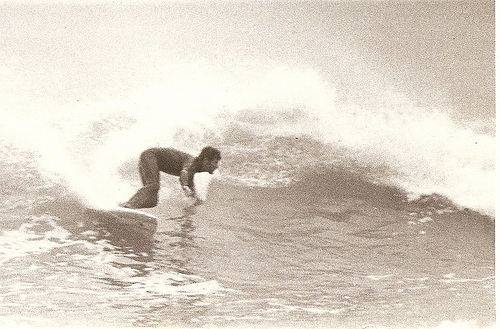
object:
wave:
[393, 73, 495, 219]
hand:
[181, 185, 192, 198]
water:
[247, 248, 492, 281]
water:
[1, 49, 412, 147]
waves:
[147, 41, 174, 137]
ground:
[441, 130, 458, 170]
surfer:
[118, 145, 221, 208]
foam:
[0, 213, 222, 325]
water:
[1, 301, 496, 326]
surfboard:
[87, 205, 157, 219]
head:
[198, 145, 220, 175]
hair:
[198, 146, 222, 160]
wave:
[2, 249, 143, 324]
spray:
[385, 2, 498, 175]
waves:
[2, 0, 39, 26]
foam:
[0, 70, 155, 160]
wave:
[8, 88, 140, 194]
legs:
[127, 149, 159, 209]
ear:
[200, 156, 208, 166]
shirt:
[159, 147, 199, 189]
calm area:
[202, 181, 474, 311]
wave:
[242, 60, 286, 139]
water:
[483, 2, 499, 216]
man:
[127, 146, 222, 209]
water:
[35, 129, 123, 204]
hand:
[192, 196, 201, 206]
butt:
[139, 148, 153, 171]